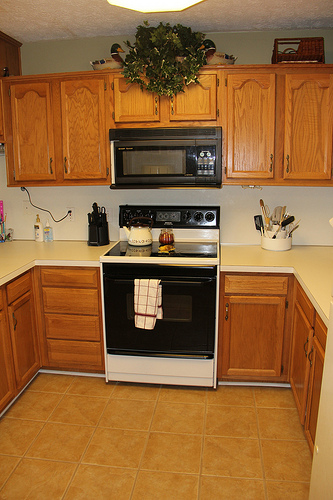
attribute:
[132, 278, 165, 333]
towel — striped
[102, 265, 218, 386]
oven — black, white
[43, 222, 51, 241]
bottle — pump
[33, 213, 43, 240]
bottle — pump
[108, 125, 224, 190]
microwave — black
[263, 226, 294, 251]
container — white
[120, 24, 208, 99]
plant — green, decoration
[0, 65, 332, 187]
cabinet — oak, brown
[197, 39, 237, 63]
duck — figure, decoy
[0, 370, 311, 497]
tile — brown, gold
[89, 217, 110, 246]
carousel — black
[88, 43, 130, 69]
duck — figure, decoy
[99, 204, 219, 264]
stove — black, white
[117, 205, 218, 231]
panel — black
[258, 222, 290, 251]
holder — white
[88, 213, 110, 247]
holder — black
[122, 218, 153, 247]
tea pot — white